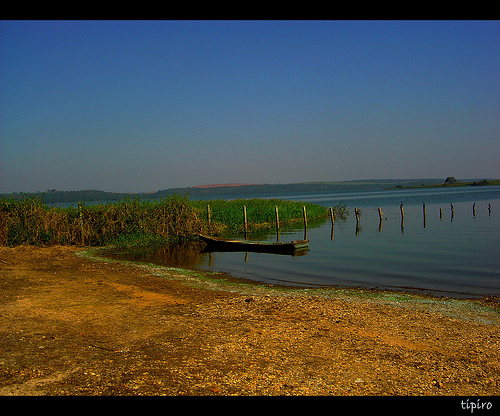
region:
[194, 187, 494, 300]
calm body of water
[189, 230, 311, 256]
empty boat in the water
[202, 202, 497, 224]
wood tree stumps sticking out of water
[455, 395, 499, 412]
text on bottom right corner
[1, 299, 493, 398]
area of dirt and moss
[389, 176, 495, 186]
small mountains in the background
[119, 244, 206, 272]
reflection of shrubs in the water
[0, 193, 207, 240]
shrubs growing by the lake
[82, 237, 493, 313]
shore of the lake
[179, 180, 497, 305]
large blue lake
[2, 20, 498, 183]
The sky is clear.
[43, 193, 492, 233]
The posts are brown.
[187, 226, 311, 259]
The boat is in the water.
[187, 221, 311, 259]
The boat is green.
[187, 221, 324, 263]
The boat is small.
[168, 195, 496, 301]
The water is calm.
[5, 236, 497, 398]
The ground is brown.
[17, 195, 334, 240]
The grass is green.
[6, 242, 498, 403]
The ground is rocky.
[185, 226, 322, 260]
The boat is by the shore.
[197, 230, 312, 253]
A boat in the water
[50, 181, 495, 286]
A large body of water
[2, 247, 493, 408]
A rocky shore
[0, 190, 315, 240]
A small area covered in tall grass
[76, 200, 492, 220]
wooden posts in the water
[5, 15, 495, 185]
A clear, blue sky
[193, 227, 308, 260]
A lone boat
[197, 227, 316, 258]
A boat docked at a rocky shore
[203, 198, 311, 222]
some lush, green grass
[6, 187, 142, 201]
A large forested area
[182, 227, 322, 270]
small boat in the water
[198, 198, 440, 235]
wooden posts sticking out of the water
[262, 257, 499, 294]
thin ripples in the water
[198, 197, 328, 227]
bright green grass growing around the water's edge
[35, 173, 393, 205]
land in the distance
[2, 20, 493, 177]
clear blue sky with no clouds in sight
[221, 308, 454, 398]
many rocks on the beach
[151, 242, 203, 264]
reflection in the water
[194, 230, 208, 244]
front of the boat is pointy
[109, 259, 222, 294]
light green line along the shore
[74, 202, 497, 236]
The posts go into the water.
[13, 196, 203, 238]
The hedges are dying.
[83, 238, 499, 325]
The shore is calm.